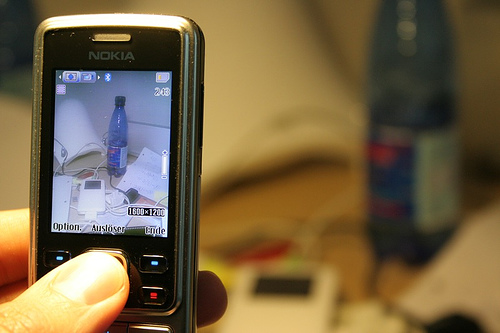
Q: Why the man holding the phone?
A: To take a picture.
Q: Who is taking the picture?
A: A person.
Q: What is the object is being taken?
A: Bottle.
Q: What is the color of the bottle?
A: Blue.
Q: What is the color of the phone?
A: Black.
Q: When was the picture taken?
A: Now.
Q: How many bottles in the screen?
A: One.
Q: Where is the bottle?
A: On the table.